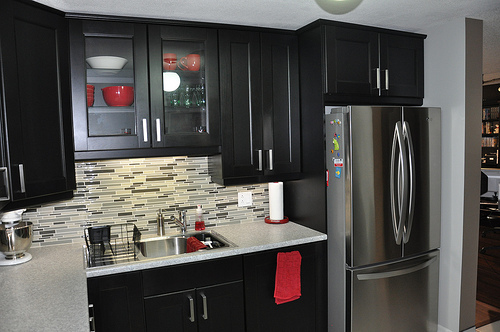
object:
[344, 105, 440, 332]
refrigerator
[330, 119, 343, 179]
magnets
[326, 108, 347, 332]
side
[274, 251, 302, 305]
towel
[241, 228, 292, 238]
countertop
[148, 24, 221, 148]
cabinet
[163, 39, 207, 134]
glass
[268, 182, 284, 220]
paper towels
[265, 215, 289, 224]
holder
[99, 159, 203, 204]
wall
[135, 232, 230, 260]
sink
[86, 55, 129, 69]
bowl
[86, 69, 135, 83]
shelf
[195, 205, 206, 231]
bottle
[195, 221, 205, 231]
soap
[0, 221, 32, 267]
mixer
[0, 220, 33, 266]
bowl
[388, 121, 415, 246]
handles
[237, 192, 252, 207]
light switch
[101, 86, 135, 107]
bowl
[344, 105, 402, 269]
door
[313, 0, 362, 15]
ceiling light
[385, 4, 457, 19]
ceiling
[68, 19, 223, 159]
cabinets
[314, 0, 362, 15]
fixture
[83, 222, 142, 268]
drainer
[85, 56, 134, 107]
dishes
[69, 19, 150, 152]
door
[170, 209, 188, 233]
faucet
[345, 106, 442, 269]
doors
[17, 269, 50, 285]
cabinet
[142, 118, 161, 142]
handles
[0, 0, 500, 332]
kitchen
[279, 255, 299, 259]
handle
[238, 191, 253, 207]
outlet